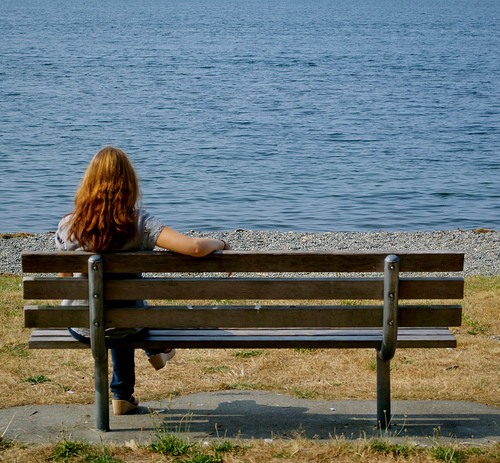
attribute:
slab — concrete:
[14, 389, 480, 447]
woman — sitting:
[54, 148, 235, 415]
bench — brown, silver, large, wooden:
[20, 250, 463, 432]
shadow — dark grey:
[110, 401, 498, 440]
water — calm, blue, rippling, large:
[2, 3, 496, 235]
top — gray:
[54, 207, 161, 336]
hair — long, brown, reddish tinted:
[69, 146, 140, 244]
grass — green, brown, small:
[2, 270, 499, 460]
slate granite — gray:
[2, 386, 496, 443]